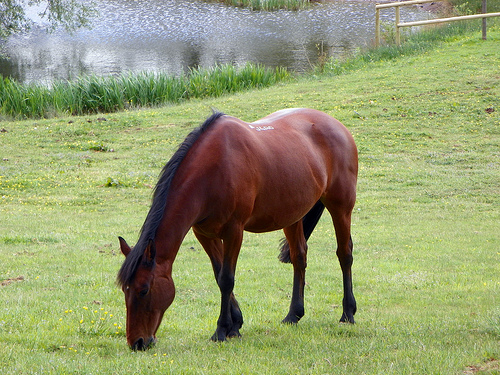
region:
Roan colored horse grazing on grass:
[96, 100, 388, 350]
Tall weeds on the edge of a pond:
[4, 59, 305, 110]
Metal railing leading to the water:
[363, 3, 498, 59]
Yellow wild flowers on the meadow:
[70, 296, 114, 354]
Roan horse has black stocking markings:
[208, 243, 380, 340]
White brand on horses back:
[242, 117, 302, 147]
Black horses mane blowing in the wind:
[116, 108, 199, 312]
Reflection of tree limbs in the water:
[0, 1, 134, 89]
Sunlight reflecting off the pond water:
[149, 3, 364, 48]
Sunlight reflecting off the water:
[171, 8, 337, 43]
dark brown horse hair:
[102, 104, 362, 354]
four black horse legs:
[204, 256, 384, 343]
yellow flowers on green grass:
[47, 293, 124, 360]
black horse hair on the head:
[114, 234, 171, 311]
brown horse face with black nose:
[105, 238, 187, 355]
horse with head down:
[87, 97, 408, 359]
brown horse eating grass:
[90, 99, 398, 354]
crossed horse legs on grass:
[196, 222, 266, 347]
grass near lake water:
[97, 5, 356, 93]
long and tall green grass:
[24, 64, 304, 113]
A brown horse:
[101, 108, 395, 357]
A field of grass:
[31, 23, 495, 368]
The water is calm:
[92, 15, 333, 80]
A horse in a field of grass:
[3, 114, 498, 369]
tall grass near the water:
[11, 55, 281, 111]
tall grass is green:
[3, 51, 298, 113]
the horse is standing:
[96, 106, 392, 356]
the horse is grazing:
[119, 98, 384, 355]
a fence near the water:
[368, 2, 498, 55]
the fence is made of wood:
[369, 5, 496, 70]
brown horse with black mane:
[117, 105, 360, 350]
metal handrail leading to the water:
[372, 0, 498, 48]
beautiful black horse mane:
[115, 107, 223, 284]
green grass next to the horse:
[410, 255, 474, 275]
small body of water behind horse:
[0, 0, 449, 90]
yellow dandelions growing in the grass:
[57, 302, 119, 349]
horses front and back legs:
[192, 191, 353, 346]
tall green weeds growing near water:
[1, 57, 289, 122]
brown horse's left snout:
[131, 335, 146, 348]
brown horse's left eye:
[136, 282, 151, 299]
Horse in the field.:
[83, 84, 414, 352]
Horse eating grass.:
[88, 79, 494, 367]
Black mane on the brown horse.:
[71, 103, 318, 316]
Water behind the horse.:
[75, 51, 430, 325]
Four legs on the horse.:
[188, 229, 429, 329]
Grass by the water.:
[42, 13, 413, 141]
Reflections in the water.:
[102, 22, 329, 107]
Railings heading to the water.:
[360, 2, 497, 59]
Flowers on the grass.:
[77, 132, 139, 202]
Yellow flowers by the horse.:
[48, 282, 122, 372]